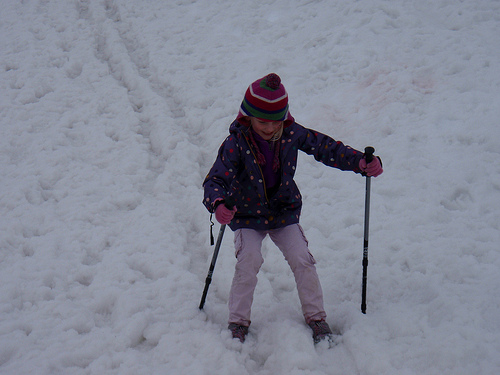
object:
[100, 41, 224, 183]
tracks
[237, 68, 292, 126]
marvin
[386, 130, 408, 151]
ground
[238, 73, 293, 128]
hat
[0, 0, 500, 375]
snow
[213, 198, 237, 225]
gloves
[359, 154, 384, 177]
gloves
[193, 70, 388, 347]
snow skiing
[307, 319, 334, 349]
shoe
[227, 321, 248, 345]
shoe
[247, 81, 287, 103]
stripe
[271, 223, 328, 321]
leg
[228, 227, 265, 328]
leg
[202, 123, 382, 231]
jacket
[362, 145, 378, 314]
pole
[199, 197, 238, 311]
poles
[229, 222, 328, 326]
pants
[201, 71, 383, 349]
child